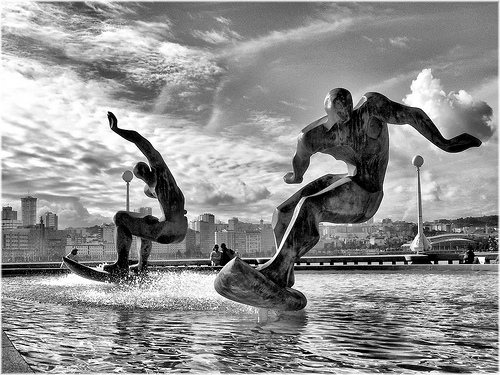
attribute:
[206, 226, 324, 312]
sculpture — stone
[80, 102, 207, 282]
surfer — metallic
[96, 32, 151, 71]
clouds — overcast, white, striated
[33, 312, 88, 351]
water — splashed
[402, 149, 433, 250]
structure — tall, cylinder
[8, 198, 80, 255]
building — high rise, here, background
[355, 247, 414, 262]
water bridge — background, narrow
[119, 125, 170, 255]
statue — background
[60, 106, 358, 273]
surfers — metallic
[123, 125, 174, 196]
arms — outstretched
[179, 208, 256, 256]
buildings — background